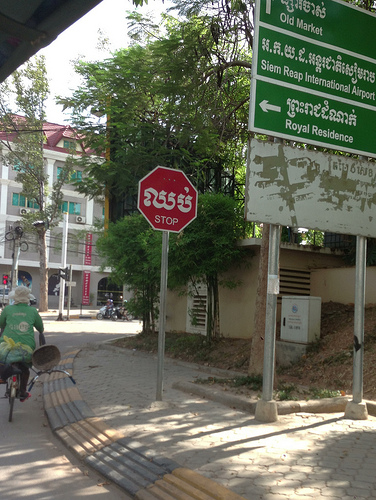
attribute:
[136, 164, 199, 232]
stop sign — octagon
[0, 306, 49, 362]
top — green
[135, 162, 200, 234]
sign — stop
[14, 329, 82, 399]
bike — another